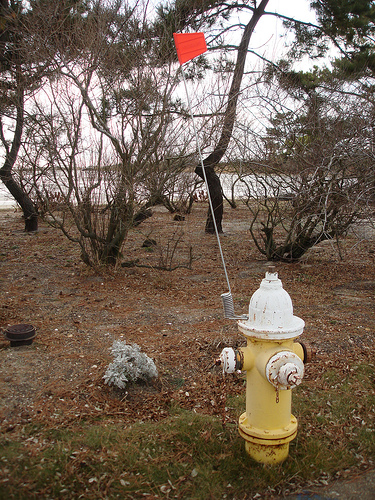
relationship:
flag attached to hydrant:
[170, 30, 237, 320] [213, 265, 312, 464]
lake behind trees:
[0, 166, 356, 211] [1, 1, 372, 272]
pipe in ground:
[4, 324, 38, 346] [0, 193, 373, 500]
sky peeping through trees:
[1, 3, 374, 170] [1, 1, 372, 272]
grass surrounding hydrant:
[1, 369, 374, 498] [213, 265, 312, 464]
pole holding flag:
[180, 64, 238, 320] [170, 30, 237, 320]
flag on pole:
[170, 30, 237, 320] [180, 64, 238, 320]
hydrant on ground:
[213, 265, 312, 464] [0, 193, 373, 500]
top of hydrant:
[236, 265, 306, 338] [213, 265, 312, 464]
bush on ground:
[102, 338, 157, 389] [0, 193, 373, 500]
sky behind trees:
[1, 3, 374, 170] [1, 1, 372, 272]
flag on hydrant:
[170, 30, 237, 320] [213, 265, 312, 464]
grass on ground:
[1, 369, 374, 498] [0, 193, 373, 500]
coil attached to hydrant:
[220, 290, 236, 321] [213, 265, 312, 464]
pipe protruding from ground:
[4, 324, 38, 346] [0, 193, 373, 500]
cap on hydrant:
[215, 347, 235, 376] [213, 265, 312, 464]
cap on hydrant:
[265, 349, 304, 389] [213, 265, 312, 464]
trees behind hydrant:
[1, 1, 372, 272] [213, 265, 312, 464]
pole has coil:
[180, 64, 238, 320] [220, 290, 236, 321]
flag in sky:
[170, 30, 237, 320] [1, 3, 374, 170]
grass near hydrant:
[1, 369, 374, 498] [213, 265, 312, 464]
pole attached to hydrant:
[180, 64, 238, 320] [213, 265, 312, 464]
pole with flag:
[180, 64, 238, 320] [170, 30, 237, 320]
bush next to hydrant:
[102, 338, 157, 389] [213, 265, 312, 464]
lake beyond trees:
[0, 166, 356, 211] [1, 1, 372, 272]